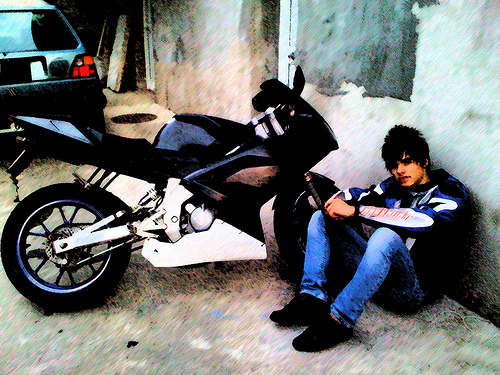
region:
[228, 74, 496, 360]
man sitting on ground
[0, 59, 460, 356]
black and white motorcycle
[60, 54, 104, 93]
car has red tail light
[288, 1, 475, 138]
paint on wall chipped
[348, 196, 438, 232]
red lettering on man's jacket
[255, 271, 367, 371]
man wearing black shoes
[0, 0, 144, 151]
the car is blue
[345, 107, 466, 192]
man's hair is black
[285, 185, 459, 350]
man wearing blue jeans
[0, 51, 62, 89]
license plate missing from car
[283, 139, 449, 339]
a boy wearing blue jeans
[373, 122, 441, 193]
a boy with dark hair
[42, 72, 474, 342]
a boy next to a motorcycle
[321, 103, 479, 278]
a boy wearing a blue and white motorcycle jacket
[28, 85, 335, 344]
a black motorcycle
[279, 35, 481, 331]
a boy leaning against a wall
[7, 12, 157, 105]
a car in the background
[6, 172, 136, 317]
back wheel on a motorcycle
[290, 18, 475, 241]
outer wall of a building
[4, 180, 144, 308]
The back tire of the motorcycle.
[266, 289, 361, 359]
The black sneakers the guy is wearing.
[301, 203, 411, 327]
The blue jeans the guy is wearing.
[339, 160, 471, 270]
The blue, white and black jacket the guy is wearing.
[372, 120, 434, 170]
The short black hair of the guy.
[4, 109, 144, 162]
The seat of the motorcycle.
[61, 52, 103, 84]
The brake light of the car.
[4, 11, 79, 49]
The car's back window.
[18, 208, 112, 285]
The spokes/rim of the back tire.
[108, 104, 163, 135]
The sewer hole next to the car.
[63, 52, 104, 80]
back light on car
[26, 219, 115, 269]
wheel on the motorcycle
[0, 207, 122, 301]
tire on the motorcycle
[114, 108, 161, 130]
water drain on sidewalk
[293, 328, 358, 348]
black shoe on foot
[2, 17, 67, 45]
back window of car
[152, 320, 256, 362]
sidewalk near the motorcycle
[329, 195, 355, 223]
one of the boy's hands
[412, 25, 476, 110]
part of the wall on building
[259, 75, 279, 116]
one of the handlebards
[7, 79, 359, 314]
Motorcycle on the street.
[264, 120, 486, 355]
Man leaning up against the building.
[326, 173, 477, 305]
Leather jacket worn by man.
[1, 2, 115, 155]
Car in the background.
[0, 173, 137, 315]
Large back tire on bike.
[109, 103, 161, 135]
Manhole cover on the street.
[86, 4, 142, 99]
Boards leaning up against the wall.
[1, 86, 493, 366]
Cement street next to building.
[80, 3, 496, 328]
Rough looking side of building.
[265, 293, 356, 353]
Black shoes on man.